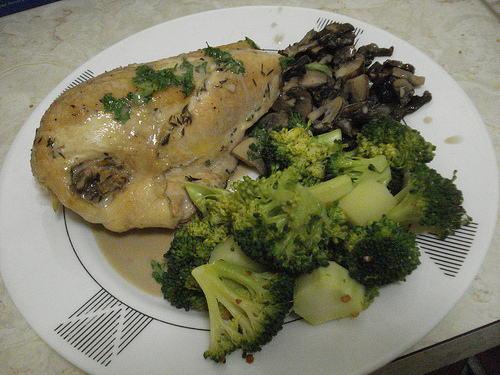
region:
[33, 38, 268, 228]
a plate of chicken breast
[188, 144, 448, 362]
cooked green broccoli on a plate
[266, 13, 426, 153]
sauteed cooked mushrooms on plate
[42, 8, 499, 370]
a white plate with food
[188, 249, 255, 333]
green stem part of broccoli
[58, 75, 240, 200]
a piece of chicken breast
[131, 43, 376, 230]
chicken breast with broccoli and mushrooms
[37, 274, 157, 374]
design on a white plate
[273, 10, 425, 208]
cooked mushrooms and broccoli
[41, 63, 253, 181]
a piece of seasoned chicken breast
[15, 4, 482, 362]
Plate of food on a white and black plate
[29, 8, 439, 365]
big piece of chicken on a plate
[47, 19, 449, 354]
stemmed broccoli on a plate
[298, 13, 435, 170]
stemmed mushrooms on a plate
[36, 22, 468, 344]
chicken with broccoli and mushrooms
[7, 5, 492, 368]
plate of food siting on a counter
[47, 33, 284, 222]
herbal baked chicken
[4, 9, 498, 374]
beige counter top in the background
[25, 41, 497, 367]
black and white stripe design on edges of white plate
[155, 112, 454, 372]
broccoli florets with pieces of stems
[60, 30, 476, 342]
dinner served on a white plate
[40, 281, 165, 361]
pattern of short and long lines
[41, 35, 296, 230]
chicken breast served with vegetables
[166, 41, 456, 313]
pieces of cut broccoli and cut mushrooms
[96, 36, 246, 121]
green garnish on top of chicken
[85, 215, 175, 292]
gravy pooling at bottom of plate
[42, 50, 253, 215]
browned skin covered in seasoning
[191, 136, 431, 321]
dark green florets next to lighter stalks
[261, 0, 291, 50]
drips on edge of plate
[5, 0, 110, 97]
stone tabletop with light brown veins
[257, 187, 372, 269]
green color broccoli is seen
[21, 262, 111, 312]
plate is white in color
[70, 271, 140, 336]
design is black in color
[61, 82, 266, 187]
brown color chicken piece is seen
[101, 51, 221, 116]
coriander leaves are seen on top of chicken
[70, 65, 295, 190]
one piece of chicken in plate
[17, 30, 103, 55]
brown color table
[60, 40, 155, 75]
plate is kept on the table.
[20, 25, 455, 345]
night time picture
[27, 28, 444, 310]
one plate meal is seen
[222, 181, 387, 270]
broccoli is green in color.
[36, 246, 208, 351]
plate is white in color.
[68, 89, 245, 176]
brown color chicken piece.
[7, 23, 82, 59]
table is white in color.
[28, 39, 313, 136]
plate is kept in the table.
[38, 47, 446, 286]
one plate of meal is seen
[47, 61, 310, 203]
one piece of chicken in seen.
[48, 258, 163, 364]
designs are drawn in black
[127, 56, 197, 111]
coriander leaves are on top of chicken.